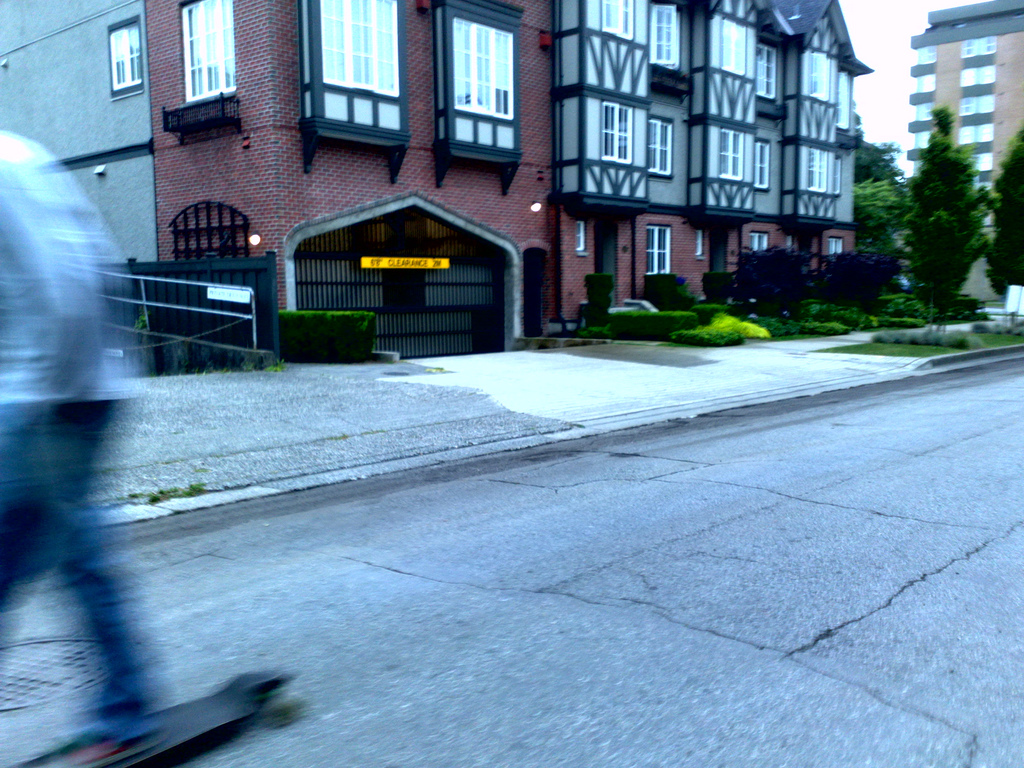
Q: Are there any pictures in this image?
A: No, there are no pictures.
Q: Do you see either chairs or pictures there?
A: No, there are no pictures or chairs.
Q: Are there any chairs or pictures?
A: No, there are no pictures or chairs.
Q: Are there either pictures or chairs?
A: No, there are no pictures or chairs.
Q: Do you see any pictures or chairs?
A: No, there are no pictures or chairs.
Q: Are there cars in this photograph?
A: No, there are no cars.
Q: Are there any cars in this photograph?
A: No, there are no cars.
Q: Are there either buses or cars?
A: No, there are no cars or buses.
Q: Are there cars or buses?
A: No, there are no cars or buses.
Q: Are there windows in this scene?
A: Yes, there is a window.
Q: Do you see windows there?
A: Yes, there is a window.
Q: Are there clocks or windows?
A: Yes, there is a window.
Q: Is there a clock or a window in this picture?
A: Yes, there is a window.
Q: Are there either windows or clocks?
A: Yes, there is a window.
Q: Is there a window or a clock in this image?
A: Yes, there is a window.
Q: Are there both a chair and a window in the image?
A: No, there is a window but no chairs.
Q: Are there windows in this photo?
A: Yes, there is a window.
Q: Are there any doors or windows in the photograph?
A: Yes, there is a window.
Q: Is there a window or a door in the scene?
A: Yes, there is a window.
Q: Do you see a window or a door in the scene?
A: Yes, there is a window.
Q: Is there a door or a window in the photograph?
A: Yes, there is a window.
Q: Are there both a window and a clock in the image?
A: No, there is a window but no clocks.